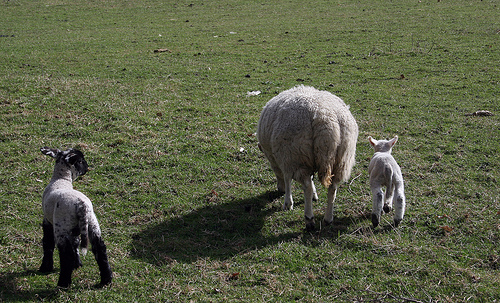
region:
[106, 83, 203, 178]
The grass is green.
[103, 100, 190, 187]
The grass is short.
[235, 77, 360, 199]
The sheep has a lot of wool.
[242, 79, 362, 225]
The sheep is white.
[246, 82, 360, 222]
The sheep is grazing.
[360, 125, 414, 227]
The lamb is white.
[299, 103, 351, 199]
The sheep has a tail.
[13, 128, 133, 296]
The sheep is black and white.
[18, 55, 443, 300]
Three sheep are in the picture.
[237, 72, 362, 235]
The sheep is eating grass.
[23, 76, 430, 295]
Three animals in the foreground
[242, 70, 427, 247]
An adult and baby sheep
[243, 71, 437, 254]
A back view of two animals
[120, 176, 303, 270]
Sheep is casting a shadow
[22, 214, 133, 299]
Fur on the animal's legs are black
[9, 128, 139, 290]
Animal's fur is black and white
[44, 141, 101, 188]
A side view of the animal's head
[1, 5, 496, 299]
Animal's are standing on a grass field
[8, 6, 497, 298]
Photo was taken in the daytime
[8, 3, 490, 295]
Photo was taken outside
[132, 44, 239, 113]
this is the grass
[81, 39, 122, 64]
the grass is green in color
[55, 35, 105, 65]
the grass is short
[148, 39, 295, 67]
there are dry leaves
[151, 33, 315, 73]
the leaves are brown in color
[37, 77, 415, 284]
these are some sheep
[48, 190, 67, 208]
the wool is white in color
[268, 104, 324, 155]
the wool is rugged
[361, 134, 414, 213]
this is a lamb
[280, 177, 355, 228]
these are sheep feet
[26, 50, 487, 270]
sheep in a field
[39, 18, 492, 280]
sheep walking in a field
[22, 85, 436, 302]
sheep walking on grass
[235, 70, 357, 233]
an adult white sheep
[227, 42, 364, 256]
an adult sheep standing in field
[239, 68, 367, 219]
a white adult sheep standing on grass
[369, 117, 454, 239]
a young white sheep walking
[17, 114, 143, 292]
a young sheep standing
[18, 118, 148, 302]
a young sheep standing in the field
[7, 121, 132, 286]
a young sheep standing on grass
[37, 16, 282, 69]
Green grass is growing.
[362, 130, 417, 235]
A white lamb.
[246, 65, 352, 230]
The sheep is white.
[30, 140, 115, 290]
The lamb is black and white.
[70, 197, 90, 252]
The lamb has a tail.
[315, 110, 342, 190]
The sheep has a tail.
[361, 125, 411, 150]
The lamb has two ears.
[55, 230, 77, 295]
The lamb's leg is black.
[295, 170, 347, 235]
The sheep has two legs.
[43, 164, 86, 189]
The lamb has a white neck.